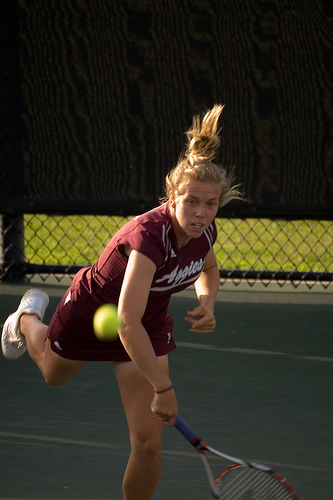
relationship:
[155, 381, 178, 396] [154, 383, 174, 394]
hair tie on hair tie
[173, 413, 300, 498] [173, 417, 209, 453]
racket has handle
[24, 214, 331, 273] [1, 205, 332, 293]
grass behind fence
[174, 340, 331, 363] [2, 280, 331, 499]
line on tennis court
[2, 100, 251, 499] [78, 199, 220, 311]
woman wearing shirt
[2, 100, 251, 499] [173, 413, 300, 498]
woman holding racket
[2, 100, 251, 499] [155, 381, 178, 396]
woman wearing hair tie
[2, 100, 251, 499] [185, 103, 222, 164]
woman has pony tail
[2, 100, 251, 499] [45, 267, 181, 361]
woman wearing skirt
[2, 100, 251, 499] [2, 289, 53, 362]
woman wearing shoe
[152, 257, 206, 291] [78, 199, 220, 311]
logo on shirt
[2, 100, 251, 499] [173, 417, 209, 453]
woman holding handle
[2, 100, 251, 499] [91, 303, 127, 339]
woman hitting ball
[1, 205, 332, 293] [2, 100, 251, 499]
fence behind woman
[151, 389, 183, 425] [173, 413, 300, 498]
hand holding racket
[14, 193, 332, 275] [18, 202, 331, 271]
area visible through fence